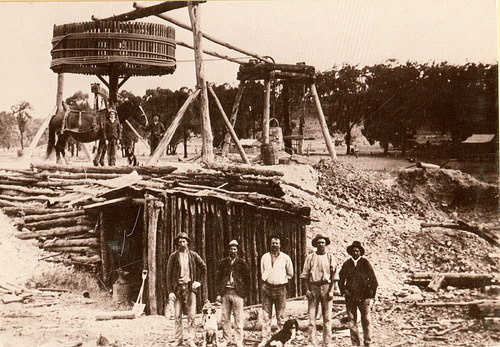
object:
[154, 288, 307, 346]
dog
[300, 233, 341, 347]
man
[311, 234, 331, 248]
hat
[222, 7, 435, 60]
sky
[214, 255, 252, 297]
coat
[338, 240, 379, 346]
men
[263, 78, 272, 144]
post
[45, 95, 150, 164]
horse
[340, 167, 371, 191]
dirt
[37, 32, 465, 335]
scene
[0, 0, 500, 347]
photo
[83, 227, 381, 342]
people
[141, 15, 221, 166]
log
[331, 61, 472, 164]
tree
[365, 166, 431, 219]
ground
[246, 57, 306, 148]
tower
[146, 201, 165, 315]
shaft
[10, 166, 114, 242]
timber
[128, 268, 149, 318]
shovel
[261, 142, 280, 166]
barrel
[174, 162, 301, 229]
contraption